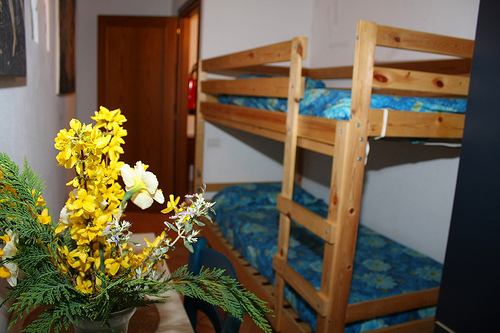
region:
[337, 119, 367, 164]
Bolts attaching separate wood sections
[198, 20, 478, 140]
Top bunk on bunk beds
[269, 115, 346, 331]
Wooden ladder on bunk beds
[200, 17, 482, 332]
Two bunk beds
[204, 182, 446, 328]
Made up bed with floral bed spread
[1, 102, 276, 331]
Yellow flowers and ferns in glass vase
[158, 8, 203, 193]
Opened doorway with red object outside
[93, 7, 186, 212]
Brown wooden door and hinges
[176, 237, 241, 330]
Backing to blue desk chair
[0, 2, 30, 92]
Edge of painting with wood frame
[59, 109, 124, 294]
A bunch of yellow flowers.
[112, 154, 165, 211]
One white rose in a flowerpot.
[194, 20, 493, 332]
A wooden bunkbed.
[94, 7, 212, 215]
Two wooden doors by the entrance.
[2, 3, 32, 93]
A picture hanging on the wall.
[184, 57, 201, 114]
A red fire extinguisher on the wall.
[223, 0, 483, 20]
A wall painte all white.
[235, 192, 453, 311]
A blue colored bed spread.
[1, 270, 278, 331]
Evergreens mixed in a flowerpot.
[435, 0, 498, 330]
The side of a television set.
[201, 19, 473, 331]
Wooden bunk beds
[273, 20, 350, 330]
Small wooden ladder for bunk beds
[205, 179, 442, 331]
blue sheets with blue daisies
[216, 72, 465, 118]
blue sheet set on a bed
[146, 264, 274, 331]
sprig on greenery in bouquet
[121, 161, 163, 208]
yellow and white colored flower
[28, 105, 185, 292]
yellow flowers in a bouquet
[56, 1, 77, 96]
picture hanging on a wall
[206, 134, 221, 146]
light switch on the wall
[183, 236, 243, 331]
blue wooden chair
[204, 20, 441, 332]
A set of bunkbeds.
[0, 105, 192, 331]
Yellow flowers on a table.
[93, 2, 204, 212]
Brown door of a room.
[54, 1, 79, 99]
Picture hanging on a wall.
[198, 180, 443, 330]
Blue bedspread on a bed.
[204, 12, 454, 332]
Bunk bed made of wood.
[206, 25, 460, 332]
Bunk beds against a wall.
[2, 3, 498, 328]
Bedroom of a house.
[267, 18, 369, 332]
Wooden ladder of a bunk bed.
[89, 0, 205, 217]
Open door to a room.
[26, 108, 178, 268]
a beautiful view of flowers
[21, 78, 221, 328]
a nice view of flowers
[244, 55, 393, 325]
a ladder to top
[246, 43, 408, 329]
a ladder to bed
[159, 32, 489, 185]
a bed on the top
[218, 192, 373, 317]
a bed in the ground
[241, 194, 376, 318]
a bed in the buttom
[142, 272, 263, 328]
green leaves of the plant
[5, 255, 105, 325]
green leaves of the tree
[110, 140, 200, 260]
white flowers in the jug